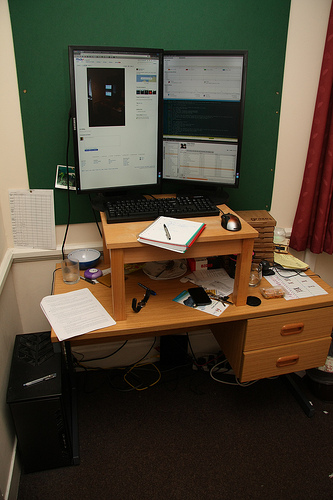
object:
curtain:
[288, 0, 333, 255]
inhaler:
[84, 268, 103, 279]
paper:
[9, 189, 56, 250]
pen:
[164, 224, 172, 240]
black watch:
[132, 289, 150, 312]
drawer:
[238, 336, 331, 383]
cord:
[119, 359, 167, 391]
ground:
[22, 360, 331, 498]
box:
[254, 227, 274, 233]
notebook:
[137, 216, 207, 254]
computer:
[67, 45, 164, 212]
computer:
[161, 49, 248, 205]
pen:
[138, 282, 157, 296]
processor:
[6, 331, 73, 474]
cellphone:
[188, 286, 212, 305]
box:
[259, 232, 274, 238]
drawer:
[243, 305, 333, 351]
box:
[235, 210, 276, 227]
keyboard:
[105, 193, 219, 224]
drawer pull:
[280, 322, 304, 336]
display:
[68, 45, 164, 213]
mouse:
[221, 213, 241, 232]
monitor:
[162, 49, 249, 204]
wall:
[3, 24, 289, 259]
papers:
[39, 287, 116, 341]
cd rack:
[253, 252, 273, 258]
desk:
[99, 193, 259, 321]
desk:
[51, 252, 333, 466]